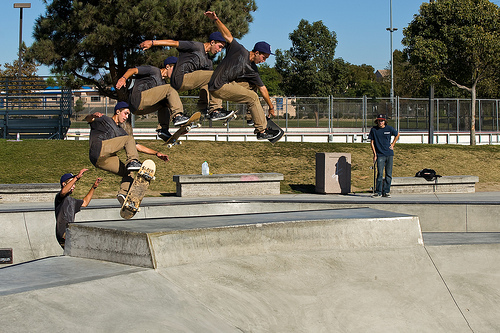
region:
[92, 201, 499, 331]
cement ramp in skate park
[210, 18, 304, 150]
person riding a skateboard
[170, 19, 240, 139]
person riding a skateboard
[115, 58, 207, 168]
person riding a skateboard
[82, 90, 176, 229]
person riding a skateboard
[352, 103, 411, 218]
person holding a skateboard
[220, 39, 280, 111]
person wearing a black shirt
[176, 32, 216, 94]
person wearing a black shirt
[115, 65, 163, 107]
person wearing a black shirt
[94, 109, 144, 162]
person wearing a black shirt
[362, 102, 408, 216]
This is a person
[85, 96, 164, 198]
This is a person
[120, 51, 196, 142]
This is a person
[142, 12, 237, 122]
This is a person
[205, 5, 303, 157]
This is a person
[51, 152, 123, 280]
This is a person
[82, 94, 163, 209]
This is a person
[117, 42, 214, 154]
This is a person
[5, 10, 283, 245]
the skater is in a time lapsed image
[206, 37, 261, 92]
the skater is wearing a short sleeve shirt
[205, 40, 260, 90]
the shirt is black in color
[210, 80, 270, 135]
the skater is wearing long pants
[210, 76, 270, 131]
the pants are brown in color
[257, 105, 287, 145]
the skater is holding the skateboard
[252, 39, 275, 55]
the skater is wearing a cap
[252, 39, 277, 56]
the cap is black in color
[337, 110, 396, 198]
the man is casting a shadow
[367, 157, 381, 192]
the man is holding a skateboard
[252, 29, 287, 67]
head of a person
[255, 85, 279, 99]
arm of a person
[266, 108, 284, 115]
hand of a person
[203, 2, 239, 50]
arm of a person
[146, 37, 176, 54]
arm of a person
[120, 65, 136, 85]
arm of a person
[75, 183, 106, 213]
arm of a person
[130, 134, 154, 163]
arm of a person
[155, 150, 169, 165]
hand of a person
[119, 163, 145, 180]
feet of a person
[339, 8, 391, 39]
this is the sky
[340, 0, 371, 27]
the sky is blue in color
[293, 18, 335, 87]
this is a tree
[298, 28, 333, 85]
the leaveas are green in color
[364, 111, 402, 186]
this is a man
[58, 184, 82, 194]
the man is light skinned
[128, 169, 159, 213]
this is a skateboard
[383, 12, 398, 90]
this is a pole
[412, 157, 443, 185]
this is a bag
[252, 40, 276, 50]
this is a cap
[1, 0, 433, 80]
bright blue clear sky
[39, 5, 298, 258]
skateboard in multiple pose shot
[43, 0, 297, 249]
skateboard in multiple pose shot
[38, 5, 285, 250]
skateboard in multiple pose shot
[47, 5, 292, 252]
skateboard in multiple pose shot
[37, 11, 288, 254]
skateboard in multiple pose shot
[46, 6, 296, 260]
skateboard in multiple pose shot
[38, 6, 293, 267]
skateboard in multiple pose shot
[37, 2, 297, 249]
skateboard in multiple pose shot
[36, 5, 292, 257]
skateboard in multiple pose shot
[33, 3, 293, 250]
skateboard in multiple pose shot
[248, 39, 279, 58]
a dark blue baseball cap